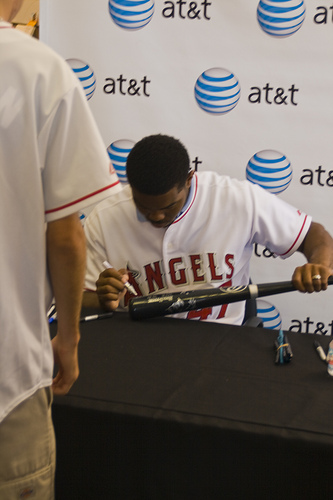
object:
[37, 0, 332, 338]
banner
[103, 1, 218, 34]
at&t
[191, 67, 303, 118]
at&t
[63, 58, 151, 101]
at&t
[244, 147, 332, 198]
at&t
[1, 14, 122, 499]
man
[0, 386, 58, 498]
shorts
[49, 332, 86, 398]
hand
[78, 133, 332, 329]
man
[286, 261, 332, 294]
hand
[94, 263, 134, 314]
hand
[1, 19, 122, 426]
shirt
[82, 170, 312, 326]
shirt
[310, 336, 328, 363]
pen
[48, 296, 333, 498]
table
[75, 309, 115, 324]
pen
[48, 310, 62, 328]
pen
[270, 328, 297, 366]
pens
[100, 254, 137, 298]
pen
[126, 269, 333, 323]
baseball bat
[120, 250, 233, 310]
angels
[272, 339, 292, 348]
rubber band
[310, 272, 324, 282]
ring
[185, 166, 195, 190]
ear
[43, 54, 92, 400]
arm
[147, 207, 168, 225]
nose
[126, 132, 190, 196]
hair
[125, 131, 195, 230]
head